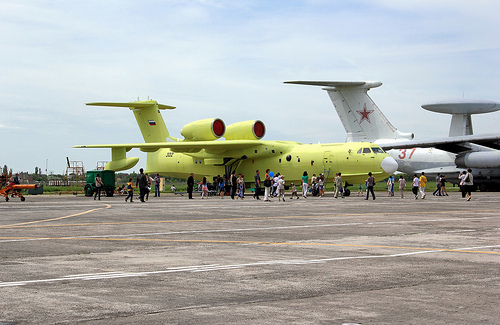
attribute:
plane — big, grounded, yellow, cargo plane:
[74, 98, 400, 192]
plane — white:
[285, 73, 498, 169]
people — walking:
[89, 172, 481, 202]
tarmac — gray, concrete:
[17, 202, 491, 256]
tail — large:
[86, 98, 189, 162]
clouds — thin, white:
[53, 21, 207, 53]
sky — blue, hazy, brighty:
[12, 4, 497, 134]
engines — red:
[174, 115, 268, 145]